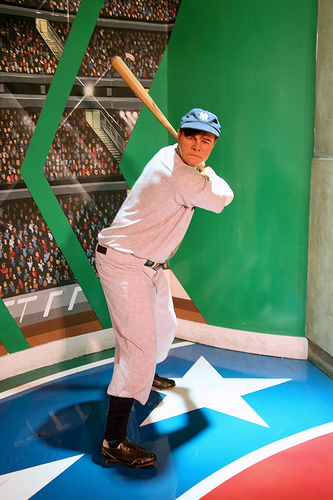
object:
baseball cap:
[178, 107, 222, 138]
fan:
[79, 143, 86, 154]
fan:
[100, 168, 108, 176]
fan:
[84, 170, 91, 177]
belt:
[95, 242, 164, 272]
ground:
[226, 142, 232, 169]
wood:
[0, 295, 207, 357]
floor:
[0, 335, 331, 498]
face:
[179, 131, 213, 167]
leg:
[101, 286, 163, 470]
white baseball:
[82, 80, 99, 106]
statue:
[92, 51, 235, 474]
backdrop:
[0, 0, 183, 339]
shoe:
[97, 434, 158, 469]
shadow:
[29, 373, 214, 478]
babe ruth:
[95, 107, 236, 469]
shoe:
[151, 370, 176, 391]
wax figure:
[92, 54, 233, 468]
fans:
[112, 168, 119, 175]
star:
[136, 352, 292, 431]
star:
[1, 451, 89, 499]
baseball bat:
[109, 53, 205, 173]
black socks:
[103, 391, 134, 442]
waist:
[94, 226, 179, 277]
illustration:
[0, 3, 181, 296]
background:
[0, 351, 333, 498]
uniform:
[95, 144, 234, 406]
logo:
[199, 111, 210, 122]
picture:
[3, 1, 179, 297]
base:
[0, 303, 309, 380]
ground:
[0, 339, 333, 500]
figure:
[92, 52, 233, 466]